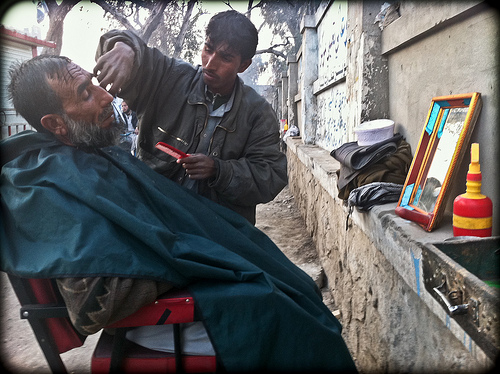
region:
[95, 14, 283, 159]
A men holding a scissor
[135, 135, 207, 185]
A red color comb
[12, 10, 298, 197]
A man cutting another man hair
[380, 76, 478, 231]
Mirror on the wall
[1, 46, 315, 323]
The man's neck was covered by green color cloth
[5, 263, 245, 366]
A red color chair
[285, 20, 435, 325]
A concrete brick wall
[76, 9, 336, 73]
Trees behind the man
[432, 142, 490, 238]
A yellow and red color sprayer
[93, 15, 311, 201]
Man wearing a coat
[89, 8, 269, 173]
Barber giving haircut outdoors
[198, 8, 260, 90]
Man with black hair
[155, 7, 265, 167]
Man holding red comb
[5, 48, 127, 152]
Man with gray hair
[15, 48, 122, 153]
Man with beard and mustache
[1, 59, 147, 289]
Man wearing blue barber's cape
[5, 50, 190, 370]
Man sitting in red barber's chair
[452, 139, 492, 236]
Spray bottle with red and yellow stripes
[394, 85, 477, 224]
Mirror with brown and blue frame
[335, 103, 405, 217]
Folded clothes stacked on ledge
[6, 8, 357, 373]
Man cutting another mans hair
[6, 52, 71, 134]
Black wet trimmed hair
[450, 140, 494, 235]
Yellow and red striped bottle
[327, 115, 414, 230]
Pile of clothing on a ledge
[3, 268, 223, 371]
Red chair with black metal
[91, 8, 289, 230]
Man holding a red comb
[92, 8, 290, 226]
Man wearing a gray jacket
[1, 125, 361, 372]
Dark teal barbers sheet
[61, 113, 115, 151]
Gray and black beard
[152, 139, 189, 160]
Small red comb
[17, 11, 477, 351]
photograph of street barber shop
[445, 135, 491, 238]
red and yellow spray bottle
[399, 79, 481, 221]
mirror leaning againt the wall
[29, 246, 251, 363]
barber chair with red cushions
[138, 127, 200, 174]
red comb in barber's hand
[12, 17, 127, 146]
man getting his beard trimmed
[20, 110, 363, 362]
blue blanket covering man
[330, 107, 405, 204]
pile of clothing on the wall ledge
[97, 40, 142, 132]
silver scissors in mans hand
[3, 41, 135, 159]
man with a beard and mustache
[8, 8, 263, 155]
Young man cutting older man's hair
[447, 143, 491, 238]
Bottle with red and yellow stripes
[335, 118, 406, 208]
Folded clothes on a ledge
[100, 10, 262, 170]
Man giving a haircut outdoors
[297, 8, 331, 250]
Stone wall with ledge